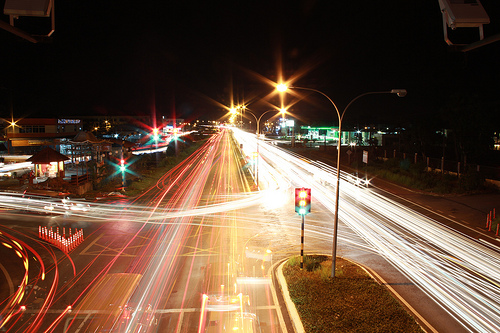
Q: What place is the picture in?
A: It is at the road.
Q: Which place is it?
A: It is a road.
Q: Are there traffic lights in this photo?
A: Yes, there is a traffic light.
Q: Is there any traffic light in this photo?
A: Yes, there is a traffic light.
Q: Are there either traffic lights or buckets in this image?
A: Yes, there is a traffic light.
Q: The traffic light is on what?
A: The traffic light is on the pole.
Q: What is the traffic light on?
A: The traffic light is on the pole.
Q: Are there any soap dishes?
A: No, there are no soap dishes.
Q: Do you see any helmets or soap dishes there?
A: No, there are no soap dishes or helmets.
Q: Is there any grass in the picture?
A: Yes, there is grass.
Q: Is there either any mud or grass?
A: Yes, there is grass.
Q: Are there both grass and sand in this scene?
A: No, there is grass but no sand.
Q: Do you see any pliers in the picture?
A: No, there are no pliers.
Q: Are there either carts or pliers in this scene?
A: No, there are no pliers or carts.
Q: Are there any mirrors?
A: No, there are no mirrors.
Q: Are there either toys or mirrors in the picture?
A: No, there are no mirrors or toys.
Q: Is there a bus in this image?
A: No, there are no buses.